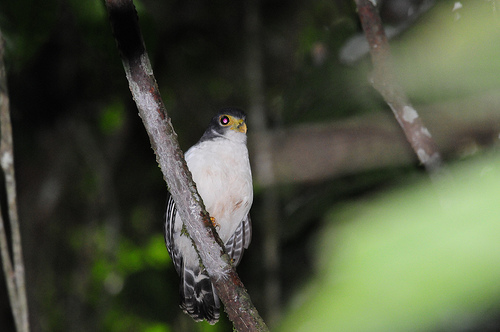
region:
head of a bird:
[208, 97, 270, 151]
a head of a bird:
[205, 102, 265, 145]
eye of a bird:
[219, 110, 229, 128]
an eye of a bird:
[218, 110, 232, 125]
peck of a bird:
[240, 124, 251, 133]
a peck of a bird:
[237, 124, 259, 135]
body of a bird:
[155, 147, 269, 252]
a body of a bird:
[149, 145, 262, 254]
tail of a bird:
[158, 241, 256, 325]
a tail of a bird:
[178, 259, 245, 325]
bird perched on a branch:
[149, 84, 252, 320]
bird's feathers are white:
[175, 143, 237, 273]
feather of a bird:
[214, 218, 260, 268]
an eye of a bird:
[214, 115, 236, 127]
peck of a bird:
[238, 118, 251, 130]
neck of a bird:
[200, 133, 247, 142]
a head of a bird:
[212, 108, 248, 135]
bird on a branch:
[145, 108, 285, 310]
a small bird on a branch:
[125, 85, 293, 327]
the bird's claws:
[200, 216, 222, 238]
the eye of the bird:
[220, 116, 231, 124]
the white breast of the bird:
[190, 134, 253, 227]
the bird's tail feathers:
[171, 265, 224, 322]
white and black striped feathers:
[226, 221, 253, 256]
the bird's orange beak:
[234, 120, 249, 133]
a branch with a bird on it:
[103, 0, 269, 330]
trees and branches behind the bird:
[0, 0, 497, 320]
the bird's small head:
[205, 107, 253, 139]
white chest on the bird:
[185, 137, 251, 251]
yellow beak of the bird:
[228, 113, 247, 131]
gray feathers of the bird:
[155, 184, 255, 325]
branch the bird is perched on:
[103, 8, 267, 330]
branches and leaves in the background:
[5, 4, 497, 329]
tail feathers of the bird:
[174, 269, 225, 326]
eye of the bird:
[217, 112, 230, 127]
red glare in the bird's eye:
[221, 117, 229, 121]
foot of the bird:
[207, 215, 216, 230]